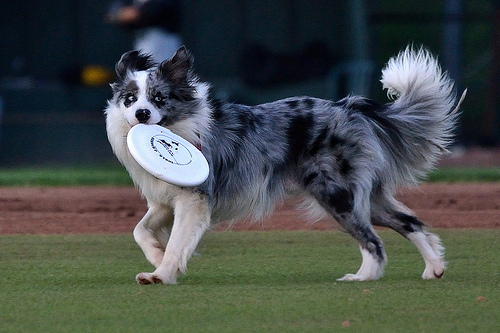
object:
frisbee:
[127, 123, 214, 189]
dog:
[101, 45, 467, 288]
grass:
[468, 235, 490, 247]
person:
[136, 19, 185, 61]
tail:
[376, 47, 454, 187]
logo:
[151, 134, 193, 165]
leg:
[131, 205, 162, 259]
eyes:
[155, 95, 161, 103]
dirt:
[52, 211, 67, 226]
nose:
[132, 107, 150, 121]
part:
[68, 170, 87, 180]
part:
[126, 133, 153, 150]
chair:
[235, 41, 359, 95]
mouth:
[117, 112, 161, 129]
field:
[0, 249, 500, 333]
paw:
[418, 262, 446, 280]